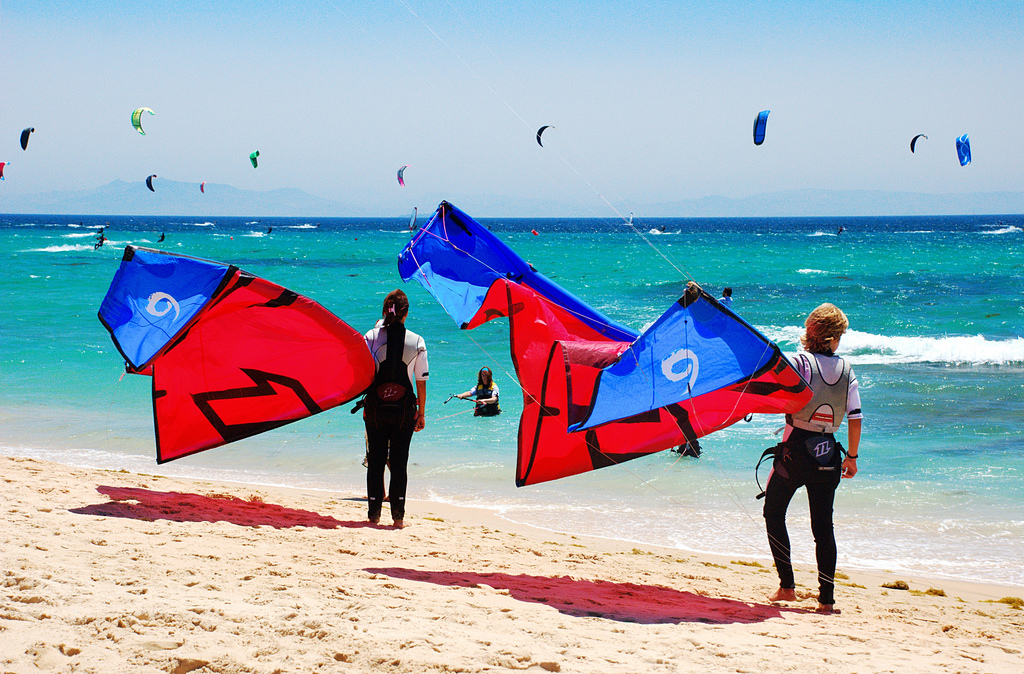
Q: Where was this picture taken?
A: A beach.